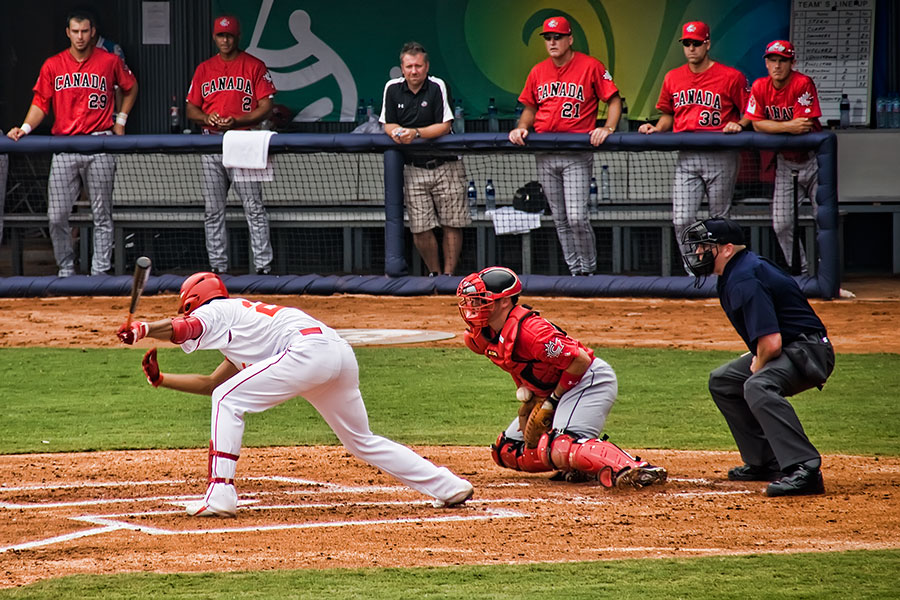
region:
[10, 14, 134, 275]
baseball player in a red jersey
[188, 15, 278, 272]
baseball player in a red jersey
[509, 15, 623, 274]
baseball player in a red jersey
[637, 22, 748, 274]
baseball player in a red jersey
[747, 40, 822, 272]
baseball player in a red jersey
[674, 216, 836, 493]
baseball referee in mask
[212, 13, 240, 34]
red and white baseball cap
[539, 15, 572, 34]
red and white baseball cap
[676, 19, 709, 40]
red and white baseball cap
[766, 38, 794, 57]
red and white baseball cap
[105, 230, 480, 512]
batter swinging the bat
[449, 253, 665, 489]
catcher behind home plate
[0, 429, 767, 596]
white lines on the field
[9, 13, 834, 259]
players standing in the dugout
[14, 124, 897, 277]
gray bench in the dugout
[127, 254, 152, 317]
black bat batter is swinging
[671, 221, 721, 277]
black face mask umpire was wearing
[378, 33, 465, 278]
man wearing black and white shirt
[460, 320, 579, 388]
red shirt catcher is wearing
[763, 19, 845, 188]
a man in uniform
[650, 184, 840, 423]
a man in uniform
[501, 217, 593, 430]
a man in uniform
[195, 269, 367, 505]
a man in uniform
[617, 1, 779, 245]
a man in uniform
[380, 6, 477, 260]
a man in uniform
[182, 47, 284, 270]
a man in uniform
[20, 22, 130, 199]
a man in uniform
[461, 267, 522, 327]
person has a head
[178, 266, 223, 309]
person has a head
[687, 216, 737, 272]
person has a head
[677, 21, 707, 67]
person has a head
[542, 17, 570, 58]
person has a head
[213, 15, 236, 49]
person has a head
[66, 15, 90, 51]
person has a head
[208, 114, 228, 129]
person has a hand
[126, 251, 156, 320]
The bat in the batter's hand.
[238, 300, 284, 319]
The number on the back of the batter's shirt.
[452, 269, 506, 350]
The face shield the catcher is wearing.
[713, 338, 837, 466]
The pants the umpire is wearing.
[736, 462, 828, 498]
The black shoes the umpire is wearing.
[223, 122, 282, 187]
The white towel draped over the railing.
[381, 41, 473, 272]
The man in khaki shorts in the dug out.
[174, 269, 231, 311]
The helmet the batter is wearing.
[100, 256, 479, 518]
person at the baseball game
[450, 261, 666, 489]
person at the baseball game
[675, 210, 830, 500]
person at the baseball game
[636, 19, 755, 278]
person at the baseball game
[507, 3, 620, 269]
person at the baseball game